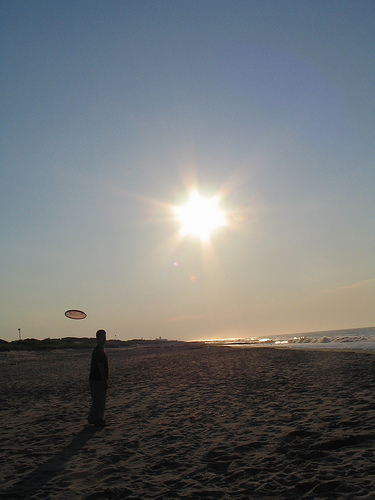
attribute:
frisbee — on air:
[63, 306, 88, 321]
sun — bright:
[168, 186, 234, 246]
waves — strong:
[242, 330, 354, 349]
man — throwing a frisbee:
[83, 327, 114, 427]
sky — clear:
[25, 47, 125, 185]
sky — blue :
[151, 37, 314, 136]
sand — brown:
[217, 367, 371, 437]